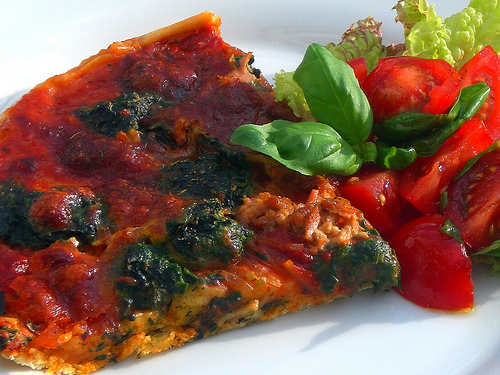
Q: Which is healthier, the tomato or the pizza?
A: The tomato is healthier than the pizza.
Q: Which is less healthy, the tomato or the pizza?
A: The pizza is less healthy than the tomato.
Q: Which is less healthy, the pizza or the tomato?
A: The pizza is less healthy than the tomato.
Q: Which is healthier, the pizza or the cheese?
A: The cheese is healthier than the pizza.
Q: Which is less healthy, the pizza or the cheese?
A: The pizza is less healthy than the cheese.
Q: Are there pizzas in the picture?
A: Yes, there is a pizza.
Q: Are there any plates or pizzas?
A: Yes, there is a pizza.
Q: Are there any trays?
A: No, there are no trays.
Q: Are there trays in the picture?
A: No, there are no trays.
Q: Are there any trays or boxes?
A: No, there are no trays or boxes.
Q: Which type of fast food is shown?
A: The fast food is a pizza.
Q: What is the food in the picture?
A: The food is a pizza.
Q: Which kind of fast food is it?
A: The food is a pizza.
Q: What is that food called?
A: This is a pizza.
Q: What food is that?
A: This is a pizza.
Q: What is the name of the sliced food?
A: The food is a pizza.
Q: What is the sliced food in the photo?
A: The food is a pizza.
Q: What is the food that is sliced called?
A: The food is a pizza.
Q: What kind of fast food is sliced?
A: The fast food is a pizza.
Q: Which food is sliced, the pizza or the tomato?
A: The pizza is sliced.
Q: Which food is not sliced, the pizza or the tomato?
A: The tomato is not sliced.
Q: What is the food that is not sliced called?
A: The food is a tomato.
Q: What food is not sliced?
A: The food is a tomato.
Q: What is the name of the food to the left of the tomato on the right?
A: The food is a pizza.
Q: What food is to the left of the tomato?
A: The food is a pizza.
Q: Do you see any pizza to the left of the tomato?
A: Yes, there is a pizza to the left of the tomato.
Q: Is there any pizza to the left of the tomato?
A: Yes, there is a pizza to the left of the tomato.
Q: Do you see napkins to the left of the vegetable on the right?
A: No, there is a pizza to the left of the tomato.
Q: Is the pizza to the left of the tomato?
A: Yes, the pizza is to the left of the tomato.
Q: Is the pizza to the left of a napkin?
A: No, the pizza is to the left of the tomato.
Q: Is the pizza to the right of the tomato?
A: No, the pizza is to the left of the tomato.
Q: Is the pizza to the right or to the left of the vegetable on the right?
A: The pizza is to the left of the tomato.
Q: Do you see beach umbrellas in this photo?
A: No, there are no beach umbrellas.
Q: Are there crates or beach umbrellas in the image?
A: No, there are no beach umbrellas or crates.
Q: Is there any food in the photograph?
A: Yes, there is food.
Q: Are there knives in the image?
A: No, there are no knives.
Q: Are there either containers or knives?
A: No, there are no knives or containers.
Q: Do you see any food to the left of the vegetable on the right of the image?
A: Yes, there is food to the left of the tomato.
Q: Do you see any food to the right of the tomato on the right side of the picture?
A: No, the food is to the left of the tomato.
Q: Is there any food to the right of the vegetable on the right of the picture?
A: No, the food is to the left of the tomato.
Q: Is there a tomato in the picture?
A: Yes, there is a tomato.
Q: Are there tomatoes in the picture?
A: Yes, there is a tomato.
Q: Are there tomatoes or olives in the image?
A: Yes, there is a tomato.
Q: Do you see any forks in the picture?
A: No, there are no forks.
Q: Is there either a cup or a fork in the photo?
A: No, there are no forks or cups.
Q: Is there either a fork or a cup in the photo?
A: No, there are no forks or cups.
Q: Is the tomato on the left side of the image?
A: No, the tomato is on the right of the image.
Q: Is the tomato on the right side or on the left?
A: The tomato is on the right of the image.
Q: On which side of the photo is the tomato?
A: The tomato is on the right of the image.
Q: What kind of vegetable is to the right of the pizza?
A: The vegetable is a tomato.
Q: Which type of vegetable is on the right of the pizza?
A: The vegetable is a tomato.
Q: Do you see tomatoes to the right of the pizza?
A: Yes, there is a tomato to the right of the pizza.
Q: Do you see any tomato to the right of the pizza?
A: Yes, there is a tomato to the right of the pizza.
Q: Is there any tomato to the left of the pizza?
A: No, the tomato is to the right of the pizza.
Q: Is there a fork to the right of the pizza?
A: No, there is a tomato to the right of the pizza.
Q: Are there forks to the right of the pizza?
A: No, there is a tomato to the right of the pizza.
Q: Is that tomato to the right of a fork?
A: No, the tomato is to the right of the pizza.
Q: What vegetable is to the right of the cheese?
A: The vegetable is a tomato.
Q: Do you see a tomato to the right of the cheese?
A: Yes, there is a tomato to the right of the cheese.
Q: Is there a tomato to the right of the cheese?
A: Yes, there is a tomato to the right of the cheese.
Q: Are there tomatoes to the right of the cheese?
A: Yes, there is a tomato to the right of the cheese.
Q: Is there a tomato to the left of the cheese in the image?
A: No, the tomato is to the right of the cheese.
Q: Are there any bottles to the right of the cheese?
A: No, there is a tomato to the right of the cheese.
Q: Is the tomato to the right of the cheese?
A: Yes, the tomato is to the right of the cheese.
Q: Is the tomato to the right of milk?
A: No, the tomato is to the right of the cheese.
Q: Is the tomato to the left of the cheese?
A: No, the tomato is to the right of the cheese.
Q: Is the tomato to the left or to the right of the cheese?
A: The tomato is to the right of the cheese.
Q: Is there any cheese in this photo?
A: Yes, there is cheese.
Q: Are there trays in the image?
A: No, there are no trays.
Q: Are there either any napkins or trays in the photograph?
A: No, there are no trays or napkins.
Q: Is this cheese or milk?
A: This is cheese.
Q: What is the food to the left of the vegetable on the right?
A: The food is cheese.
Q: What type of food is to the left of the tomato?
A: The food is cheese.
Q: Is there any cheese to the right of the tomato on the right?
A: No, the cheese is to the left of the tomato.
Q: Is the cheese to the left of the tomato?
A: Yes, the cheese is to the left of the tomato.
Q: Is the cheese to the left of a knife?
A: No, the cheese is to the left of the tomato.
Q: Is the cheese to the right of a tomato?
A: No, the cheese is to the left of a tomato.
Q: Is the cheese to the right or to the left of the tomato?
A: The cheese is to the left of the tomato.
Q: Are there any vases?
A: No, there are no vases.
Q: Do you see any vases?
A: No, there are no vases.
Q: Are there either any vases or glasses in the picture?
A: No, there are no vases or glasses.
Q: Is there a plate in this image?
A: Yes, there is a plate.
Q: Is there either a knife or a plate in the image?
A: Yes, there is a plate.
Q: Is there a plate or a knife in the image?
A: Yes, there is a plate.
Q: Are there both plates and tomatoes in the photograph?
A: Yes, there are both a plate and a tomato.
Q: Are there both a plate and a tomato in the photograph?
A: Yes, there are both a plate and a tomato.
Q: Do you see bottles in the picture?
A: No, there are no bottles.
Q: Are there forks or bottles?
A: No, there are no bottles or forks.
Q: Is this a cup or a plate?
A: This is a plate.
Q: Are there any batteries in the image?
A: No, there are no batteries.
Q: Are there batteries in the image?
A: No, there are no batteries.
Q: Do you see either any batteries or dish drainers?
A: No, there are no batteries or dish drainers.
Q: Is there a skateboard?
A: No, there are no skateboards.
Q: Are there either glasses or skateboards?
A: No, there are no skateboards or glasses.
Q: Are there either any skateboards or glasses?
A: No, there are no skateboards or glasses.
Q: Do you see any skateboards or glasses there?
A: No, there are no skateboards or glasses.